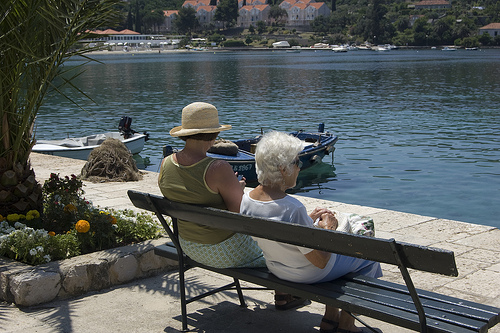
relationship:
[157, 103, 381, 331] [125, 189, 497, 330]
ladies on bench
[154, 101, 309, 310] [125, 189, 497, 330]
lady on bench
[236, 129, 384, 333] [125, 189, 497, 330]
ladies on bench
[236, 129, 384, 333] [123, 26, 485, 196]
ladies by lake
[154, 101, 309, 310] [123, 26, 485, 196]
lady by lake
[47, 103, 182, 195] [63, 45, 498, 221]
boat on water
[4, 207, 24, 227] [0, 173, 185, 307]
flower in bed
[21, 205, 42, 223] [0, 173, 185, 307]
flower in bed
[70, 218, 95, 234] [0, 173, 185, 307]
flower in bed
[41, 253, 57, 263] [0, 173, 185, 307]
flower in bed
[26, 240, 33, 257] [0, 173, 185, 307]
flower in bed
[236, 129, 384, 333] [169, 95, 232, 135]
ladies wearing hat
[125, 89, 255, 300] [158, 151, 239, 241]
lady wearing tank top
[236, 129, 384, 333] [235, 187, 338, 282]
ladies wearing shirt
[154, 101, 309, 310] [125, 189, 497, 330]
lady sitting on bench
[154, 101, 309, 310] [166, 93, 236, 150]
lady wearing hat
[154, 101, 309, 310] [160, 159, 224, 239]
lady wearing shirt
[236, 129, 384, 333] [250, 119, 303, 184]
ladies has hair.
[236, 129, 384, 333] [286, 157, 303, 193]
ladies has face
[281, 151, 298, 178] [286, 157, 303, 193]
glasses on face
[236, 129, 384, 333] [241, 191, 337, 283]
ladies wearing shirt